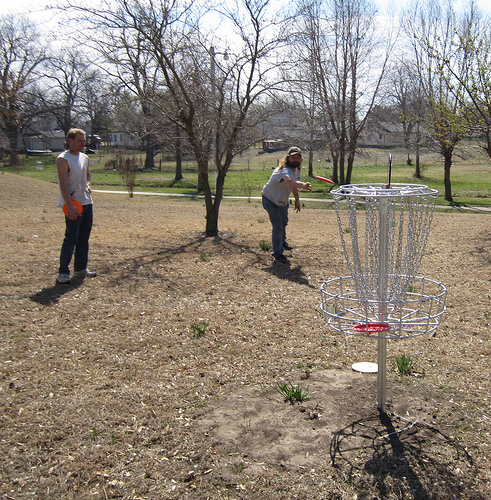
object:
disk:
[350, 359, 380, 372]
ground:
[1, 173, 489, 498]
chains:
[330, 188, 441, 321]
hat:
[287, 147, 300, 156]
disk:
[314, 175, 335, 183]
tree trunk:
[442, 156, 454, 205]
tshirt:
[261, 165, 300, 207]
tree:
[404, 0, 486, 197]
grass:
[17, 150, 489, 207]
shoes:
[55, 273, 72, 283]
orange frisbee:
[312, 175, 336, 185]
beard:
[286, 159, 302, 169]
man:
[57, 126, 97, 284]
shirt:
[56, 150, 92, 207]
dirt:
[0, 170, 490, 497]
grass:
[273, 375, 310, 406]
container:
[313, 182, 452, 350]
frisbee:
[62, 200, 83, 216]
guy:
[262, 144, 314, 266]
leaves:
[409, 0, 490, 141]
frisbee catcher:
[315, 158, 453, 433]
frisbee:
[351, 320, 389, 333]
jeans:
[58, 204, 95, 280]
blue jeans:
[58, 204, 96, 277]